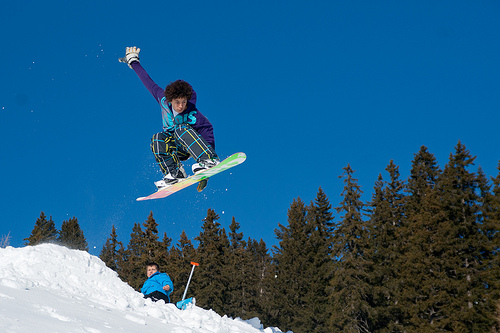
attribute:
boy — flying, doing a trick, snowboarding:
[118, 46, 218, 191]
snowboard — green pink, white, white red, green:
[136, 152, 247, 201]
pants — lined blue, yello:
[150, 123, 216, 174]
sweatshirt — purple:
[130, 60, 213, 149]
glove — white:
[117, 46, 140, 66]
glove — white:
[196, 178, 208, 192]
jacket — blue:
[140, 272, 173, 300]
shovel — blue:
[176, 260, 199, 310]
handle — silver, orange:
[180, 260, 199, 301]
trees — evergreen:
[23, 139, 500, 332]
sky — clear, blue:
[1, 0, 500, 259]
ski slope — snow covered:
[1, 242, 282, 332]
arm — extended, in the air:
[118, 46, 164, 103]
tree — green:
[326, 161, 385, 332]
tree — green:
[260, 197, 328, 332]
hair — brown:
[164, 80, 195, 102]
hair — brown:
[145, 261, 160, 270]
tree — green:
[198, 208, 227, 318]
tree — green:
[27, 210, 46, 244]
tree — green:
[65, 217, 88, 252]